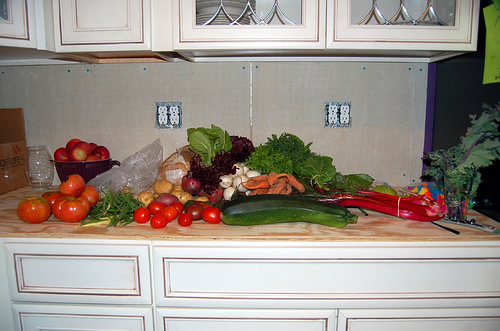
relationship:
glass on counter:
[23, 144, 55, 190] [8, 169, 498, 269]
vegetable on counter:
[178, 210, 192, 225] [13, 167, 481, 265]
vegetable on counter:
[14, 103, 500, 225] [13, 167, 481, 265]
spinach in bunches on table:
[188, 119, 240, 175] [5, 172, 477, 324]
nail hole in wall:
[358, 64, 367, 76] [1, 58, 421, 203]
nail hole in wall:
[406, 62, 411, 73] [1, 58, 421, 203]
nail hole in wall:
[415, 63, 423, 75] [1, 58, 421, 203]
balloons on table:
[409, 181, 441, 201] [1, 188, 498, 329]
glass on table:
[23, 144, 55, 190] [0, 190, 471, 241]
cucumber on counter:
[228, 196, 350, 233] [248, 222, 335, 249]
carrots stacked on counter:
[239, 167, 306, 201] [0, 180, 498, 245]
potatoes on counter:
[196, 196, 208, 201] [2, 185, 499, 242]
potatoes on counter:
[171, 190, 191, 202] [2, 185, 499, 242]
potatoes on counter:
[151, 180, 172, 193] [2, 185, 499, 242]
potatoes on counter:
[138, 191, 154, 206] [2, 185, 499, 242]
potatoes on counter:
[181, 177, 199, 192] [2, 185, 499, 242]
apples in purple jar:
[54, 138, 109, 158] [47, 158, 120, 180]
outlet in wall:
[325, 102, 350, 128] [5, 2, 498, 329]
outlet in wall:
[326, 103, 351, 126] [3, 57, 435, 183]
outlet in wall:
[325, 102, 361, 129] [48, 73, 421, 159]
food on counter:
[16, 118, 483, 235] [0, 182, 480, 241]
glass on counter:
[23, 144, 55, 190] [20, 101, 459, 271]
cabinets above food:
[2, 0, 497, 70] [16, 118, 483, 235]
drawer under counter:
[9, 245, 151, 304] [7, 238, 492, 320]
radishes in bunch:
[312, 173, 459, 230] [342, 171, 452, 225]